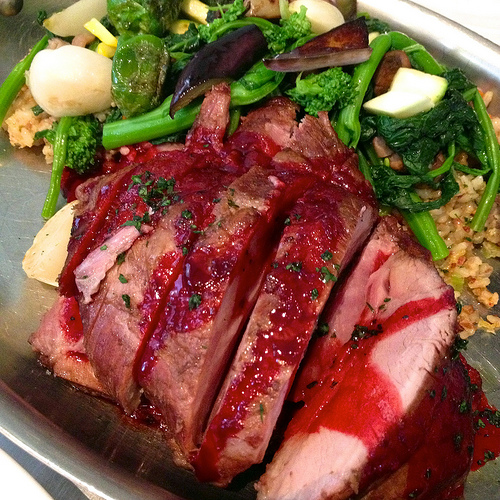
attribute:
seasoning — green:
[98, 170, 498, 467]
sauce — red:
[179, 254, 213, 307]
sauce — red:
[171, 225, 243, 343]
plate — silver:
[2, 0, 483, 499]